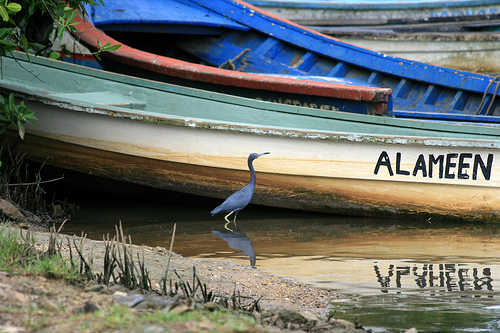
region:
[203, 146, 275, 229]
a blue heron standing in the water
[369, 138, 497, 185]
the word Alameen painted on the side of a boat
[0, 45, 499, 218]
a green and white canoe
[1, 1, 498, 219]
a bunch of canoes docked on shore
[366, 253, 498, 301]
the reflection of the word Alameen in the water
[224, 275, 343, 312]
a pile of small pebbles and sand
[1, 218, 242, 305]
grass growing on the shoreline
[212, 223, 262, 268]
the bird's reflection in the water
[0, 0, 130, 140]
leaves from a nearby tree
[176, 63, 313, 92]
worn red paint on the side of the canoe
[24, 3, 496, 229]
a few row boats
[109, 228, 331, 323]
a sandy shore line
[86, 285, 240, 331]
a few patches of grass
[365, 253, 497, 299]
some writings reflection in the water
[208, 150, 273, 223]
a blue grey bird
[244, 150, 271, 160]
a bird with a long beak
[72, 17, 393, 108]
a red edge of a boat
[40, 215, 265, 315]
a few spiky plants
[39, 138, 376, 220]
an algae covered boat bottom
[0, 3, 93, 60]
a few light green leaves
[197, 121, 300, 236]
the bird is gray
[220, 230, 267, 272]
a reflection of the bird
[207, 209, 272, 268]
a reflection of the bird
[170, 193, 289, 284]
a reflection of the bird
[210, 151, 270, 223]
the bird next to the boat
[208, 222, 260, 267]
the reflection of the bird in the water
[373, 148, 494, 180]
the letters on the side of the boat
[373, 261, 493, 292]
the reflection of the letters in the water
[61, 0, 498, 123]
the red and blue boat in the back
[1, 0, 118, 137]
the green leaves from the tree branch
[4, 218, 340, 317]
the dirt near the water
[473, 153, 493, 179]
the black N on the boat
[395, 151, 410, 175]
the black L on the boat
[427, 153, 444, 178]
the black M on the boat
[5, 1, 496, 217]
two boats in water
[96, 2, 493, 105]
blue interior of boat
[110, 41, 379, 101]
red trim on boat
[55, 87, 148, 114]
seat inside of boat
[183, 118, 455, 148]
worn paint on trim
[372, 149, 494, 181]
black hand painted word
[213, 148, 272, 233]
purple bird in water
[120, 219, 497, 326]
calm water with reflection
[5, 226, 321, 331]
dirt and grass on shore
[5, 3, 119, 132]
green leaves on tree